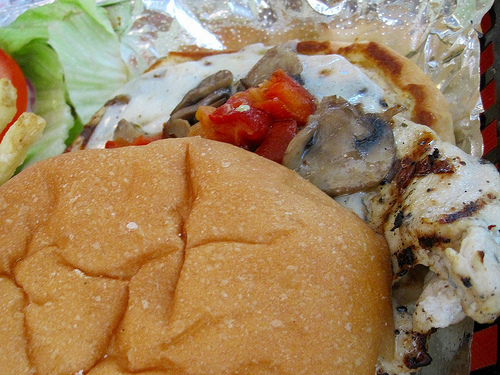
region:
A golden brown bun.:
[1, 140, 395, 373]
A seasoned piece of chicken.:
[342, 111, 499, 373]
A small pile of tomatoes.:
[188, 65, 320, 162]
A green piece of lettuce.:
[0, 0, 132, 179]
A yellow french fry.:
[0, 110, 46, 186]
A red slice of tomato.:
[0, 48, 28, 143]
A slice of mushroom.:
[283, 100, 398, 198]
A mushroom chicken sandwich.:
[0, 35, 499, 373]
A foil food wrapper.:
[0, 0, 492, 158]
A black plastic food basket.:
[478, 1, 499, 168]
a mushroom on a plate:
[280, 104, 396, 191]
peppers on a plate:
[202, 77, 316, 163]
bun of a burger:
[1, 138, 399, 374]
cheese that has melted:
[381, 123, 496, 323]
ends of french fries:
[1, 80, 44, 178]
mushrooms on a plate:
[172, 70, 233, 135]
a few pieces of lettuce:
[7, 3, 122, 153]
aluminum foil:
[106, 0, 485, 150]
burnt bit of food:
[403, 144, 450, 180]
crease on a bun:
[167, 148, 199, 305]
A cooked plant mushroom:
[283, 100, 399, 195]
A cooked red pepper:
[213, 67, 302, 149]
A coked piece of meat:
[392, 128, 493, 333]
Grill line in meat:
[441, 183, 498, 235]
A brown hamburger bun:
[18, 136, 373, 362]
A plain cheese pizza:
[73, 47, 456, 140]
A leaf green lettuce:
[3, 0, 137, 146]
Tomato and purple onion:
[1, 46, 36, 127]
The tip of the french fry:
[1, 110, 45, 170]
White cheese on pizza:
[313, 51, 383, 99]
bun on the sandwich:
[22, 153, 332, 372]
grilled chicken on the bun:
[412, 171, 462, 235]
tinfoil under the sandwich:
[434, 52, 468, 83]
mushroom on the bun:
[280, 93, 400, 186]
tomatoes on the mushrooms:
[220, 89, 292, 144]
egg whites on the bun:
[140, 81, 159, 118]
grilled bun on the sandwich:
[360, 43, 395, 78]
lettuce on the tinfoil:
[46, 35, 95, 100]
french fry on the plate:
[12, 110, 52, 167]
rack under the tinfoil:
[483, 66, 497, 122]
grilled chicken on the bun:
[410, 169, 490, 255]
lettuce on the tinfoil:
[20, 23, 120, 70]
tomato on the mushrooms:
[225, 90, 291, 139]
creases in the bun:
[127, 191, 234, 305]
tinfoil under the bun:
[202, 7, 272, 33]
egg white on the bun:
[146, 72, 171, 116]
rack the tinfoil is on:
[471, 39, 498, 84]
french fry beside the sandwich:
[0, 113, 57, 155]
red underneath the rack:
[481, 87, 494, 105]